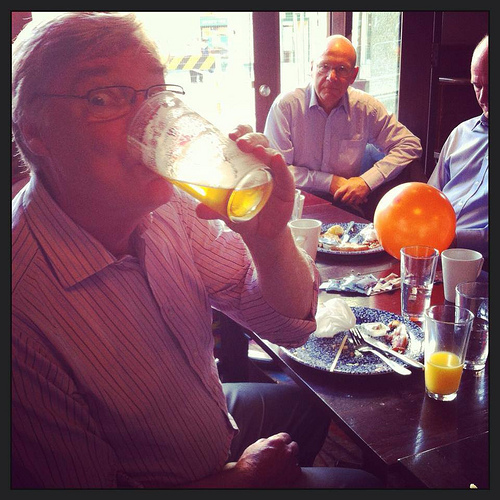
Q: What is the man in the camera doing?
A: Drinking a beer.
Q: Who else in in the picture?
A: Two other men.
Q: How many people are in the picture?
A: Three.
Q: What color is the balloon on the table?
A: Orange.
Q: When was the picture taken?
A: During the day.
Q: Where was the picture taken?
A: In a restaurant.